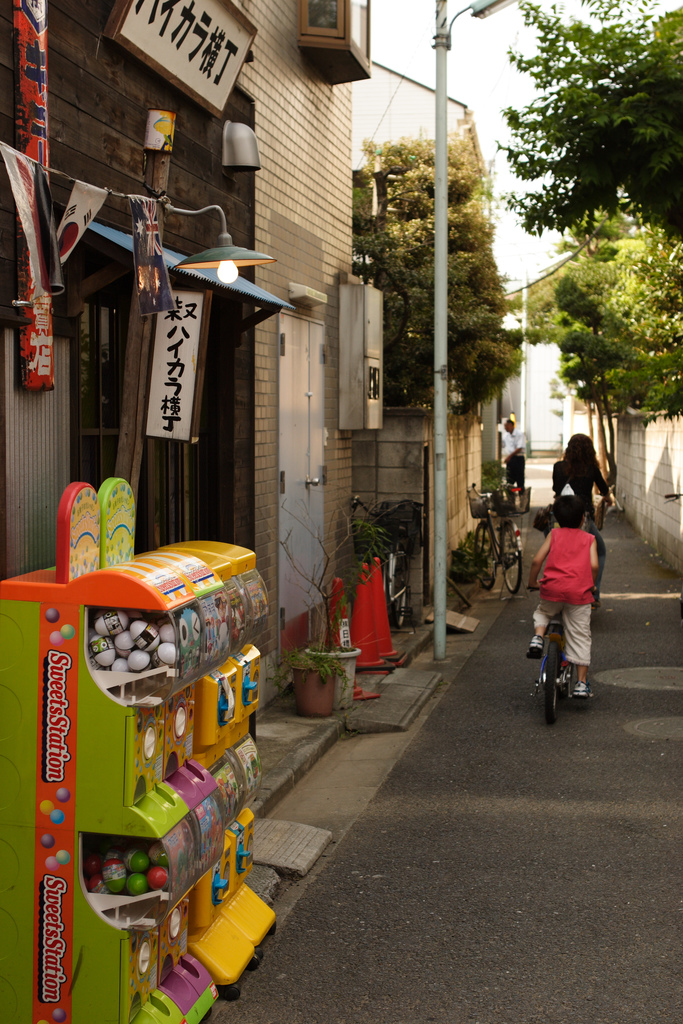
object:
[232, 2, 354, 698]
wall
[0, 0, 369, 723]
building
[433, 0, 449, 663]
light pole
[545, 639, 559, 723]
tire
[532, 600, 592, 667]
shorts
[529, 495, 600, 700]
boy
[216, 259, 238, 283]
light bulb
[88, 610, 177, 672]
toy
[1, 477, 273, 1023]
vending machine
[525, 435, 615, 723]
people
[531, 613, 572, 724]
bicycle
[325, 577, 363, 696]
cones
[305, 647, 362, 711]
flower pot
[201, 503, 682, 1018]
ally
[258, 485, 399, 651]
plant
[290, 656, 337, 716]
pot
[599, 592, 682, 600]
light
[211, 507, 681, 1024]
ground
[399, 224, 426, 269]
leaves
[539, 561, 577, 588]
wrinkles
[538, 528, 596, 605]
shirt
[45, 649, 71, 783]
writing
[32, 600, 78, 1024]
background